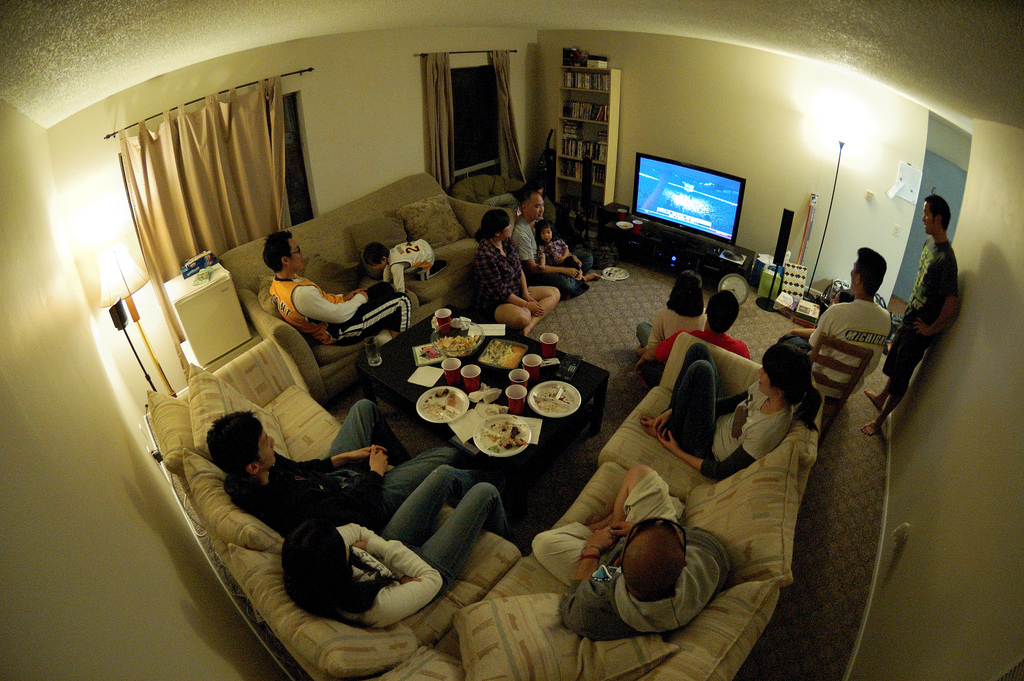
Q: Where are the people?
A: In the living room.